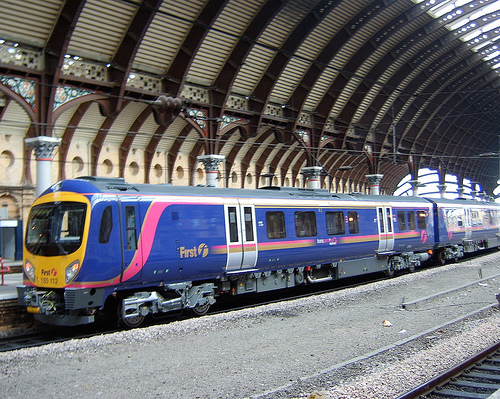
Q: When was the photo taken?
A: Daytime.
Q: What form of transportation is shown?
A: Train.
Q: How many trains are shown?
A: One.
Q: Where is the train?
A: On the tracks.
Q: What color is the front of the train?
A: Yellow.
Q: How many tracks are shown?
A: Two.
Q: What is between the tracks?
A: Gravel.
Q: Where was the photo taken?
A: At a large train station.